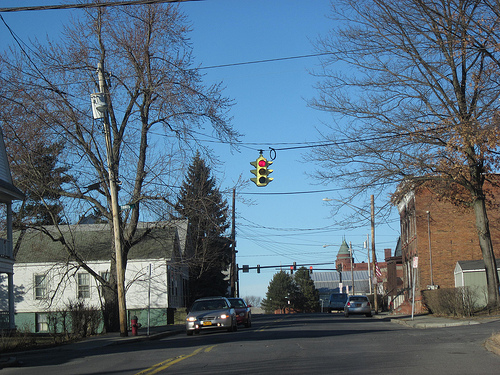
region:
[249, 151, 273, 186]
Traffic light in the air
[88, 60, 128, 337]
Electric pole on the sidewalk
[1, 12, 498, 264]
Electric lines in the sky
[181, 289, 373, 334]
Cars on the road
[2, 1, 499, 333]
Trees on the sidewalk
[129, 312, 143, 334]
Fire hydrant on the sidewalk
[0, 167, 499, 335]
Buildings on the sides of the road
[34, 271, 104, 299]
Windows on the white house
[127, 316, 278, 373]
Yellow marks on the road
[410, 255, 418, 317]
Sign on a stick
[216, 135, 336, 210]
Red light on traffic signal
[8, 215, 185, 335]
House with green paint at bottom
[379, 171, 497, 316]
red brick building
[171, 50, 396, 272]
A cloudless blue sky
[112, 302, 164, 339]
A red and green fire hydrant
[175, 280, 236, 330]
A car with a yellow license plate on front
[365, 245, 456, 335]
No parking sign on sidewalk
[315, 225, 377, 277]
Building with green cone shaped roof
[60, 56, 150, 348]
Power pull with transformer at top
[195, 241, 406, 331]
Trees that appear to be in middle of street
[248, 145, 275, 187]
glowing red traffic light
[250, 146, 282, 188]
traffic light box hanging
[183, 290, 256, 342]
two cars at the intersection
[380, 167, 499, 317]
two story brick building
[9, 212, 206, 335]
white and green house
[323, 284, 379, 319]
two parked cars on the street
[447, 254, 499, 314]
small grey shed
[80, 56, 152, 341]
tall wooden light pole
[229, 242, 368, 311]
large traffic light down the block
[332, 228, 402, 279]
brick tower in the distance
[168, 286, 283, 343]
Two cars on a road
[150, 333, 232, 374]
Yellow line on pavement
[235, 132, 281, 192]
Stop light in the air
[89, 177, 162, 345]
Power pole by a road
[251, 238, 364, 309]
Lights over a road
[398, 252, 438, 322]
Sign by a road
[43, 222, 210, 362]
White building by a road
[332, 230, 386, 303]
Brick building by a road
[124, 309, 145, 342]
Red hydrant by a street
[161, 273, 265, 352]
Cars on a street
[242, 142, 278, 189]
yellow traffic light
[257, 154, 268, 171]
red light on traffic light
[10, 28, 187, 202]
tree with no leaves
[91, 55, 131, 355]
tall wooden post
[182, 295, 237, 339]
car on concrete road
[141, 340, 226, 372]
yellow lines painted on concrete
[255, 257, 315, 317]
tree with green leaves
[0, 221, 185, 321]
house with white walls and grey roof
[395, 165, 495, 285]
brown brick building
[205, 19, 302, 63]
clear blue cloudless sky